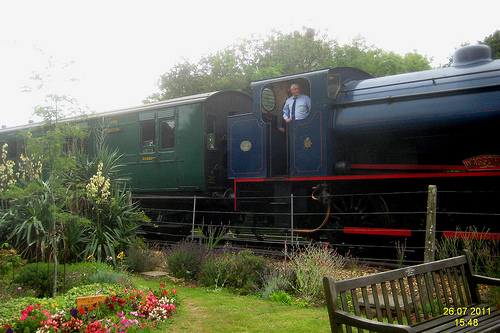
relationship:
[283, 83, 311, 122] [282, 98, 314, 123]
man wears shirt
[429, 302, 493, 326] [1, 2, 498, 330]
date of a picture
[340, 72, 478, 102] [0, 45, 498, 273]
railing on a train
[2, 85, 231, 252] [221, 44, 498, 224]
car following engine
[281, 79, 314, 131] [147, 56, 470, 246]
man inside train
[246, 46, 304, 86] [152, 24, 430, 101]
leaves on tree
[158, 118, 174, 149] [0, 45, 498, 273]
window on train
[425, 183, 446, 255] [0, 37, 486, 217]
fence post near train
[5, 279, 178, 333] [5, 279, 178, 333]
flower in flower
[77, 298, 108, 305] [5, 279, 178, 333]
flower in flower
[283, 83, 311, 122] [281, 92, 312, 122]
man wearing shirt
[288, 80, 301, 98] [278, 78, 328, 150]
head of man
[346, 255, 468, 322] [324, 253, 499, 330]
back of bench